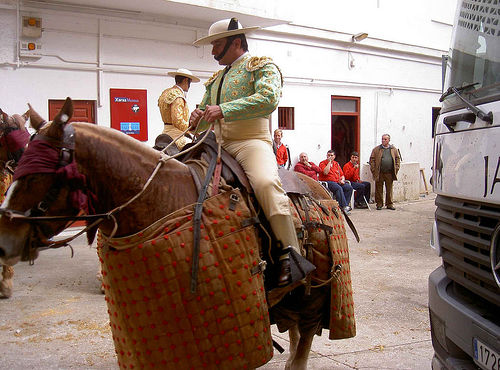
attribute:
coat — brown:
[367, 140, 402, 182]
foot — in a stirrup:
[269, 246, 318, 293]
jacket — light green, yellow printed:
[202, 62, 287, 149]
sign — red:
[112, 80, 146, 143]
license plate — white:
[473, 340, 484, 359]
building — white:
[274, 0, 427, 158]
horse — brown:
[31, 114, 340, 344]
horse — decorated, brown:
[4, 94, 372, 368]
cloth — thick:
[104, 196, 275, 353]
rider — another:
[145, 64, 199, 146]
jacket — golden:
[151, 70, 197, 154]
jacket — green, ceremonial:
[199, 58, 286, 125]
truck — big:
[434, 4, 486, 350]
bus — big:
[435, 10, 485, 320]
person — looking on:
[270, 126, 288, 170]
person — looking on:
[294, 147, 321, 195]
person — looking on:
[321, 145, 342, 187]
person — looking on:
[345, 147, 367, 190]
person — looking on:
[372, 129, 403, 206]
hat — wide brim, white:
[191, 16, 261, 56]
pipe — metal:
[90, 19, 107, 111]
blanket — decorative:
[92, 192, 356, 368]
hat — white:
[185, 15, 263, 50]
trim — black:
[225, 18, 239, 33]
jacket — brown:
[369, 144, 399, 180]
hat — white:
[191, 17, 261, 47]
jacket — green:
[192, 52, 282, 132]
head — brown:
[2, 97, 93, 270]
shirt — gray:
[376, 144, 396, 181]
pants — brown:
[370, 169, 398, 209]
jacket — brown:
[366, 141, 405, 181]